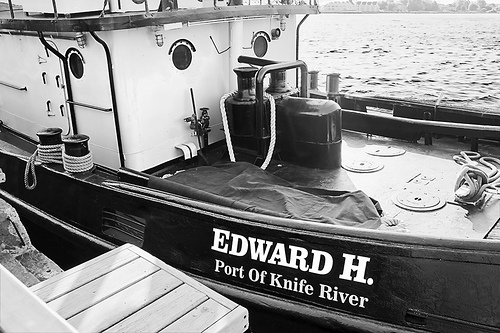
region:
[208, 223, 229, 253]
a letter is written in white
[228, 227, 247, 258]
a letter is written in white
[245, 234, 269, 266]
a letter is written in white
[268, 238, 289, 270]
a letter is written in white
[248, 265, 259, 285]
a letter is written in white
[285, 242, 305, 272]
a letter is written in white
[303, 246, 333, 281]
a letter is written in white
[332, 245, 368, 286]
a letter is written in white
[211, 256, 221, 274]
a letter is written in white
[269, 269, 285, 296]
a letter is written in white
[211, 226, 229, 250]
a letter is written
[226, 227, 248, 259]
a letter is written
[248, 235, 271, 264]
a letter is written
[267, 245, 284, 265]
a letter is written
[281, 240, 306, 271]
a letter is written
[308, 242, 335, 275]
a letter is written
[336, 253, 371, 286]
a letter is written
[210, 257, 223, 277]
a letter is written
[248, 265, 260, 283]
a letter is written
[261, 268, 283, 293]
a letter is written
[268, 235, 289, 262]
a letter is written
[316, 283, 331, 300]
a letter is written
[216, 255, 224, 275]
a letter is written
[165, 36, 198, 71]
A portal in a boat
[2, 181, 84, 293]
A stone stepping going down to the river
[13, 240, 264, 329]
A wooden dock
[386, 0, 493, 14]
Trees on the other side of a river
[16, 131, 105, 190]
Rope wrapped round and round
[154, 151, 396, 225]
A trap laid out on the deck of a boat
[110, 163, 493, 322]
The name of a boat painted on its side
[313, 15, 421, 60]
Sunlight shining on water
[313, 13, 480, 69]
A flowing river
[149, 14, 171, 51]
A light with a protective cage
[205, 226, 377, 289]
EDWARD H.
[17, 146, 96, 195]
two windy ship ropes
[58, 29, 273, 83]
three dark portholes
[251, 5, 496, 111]
one ocean with small wavelets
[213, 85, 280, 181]
big thick white rope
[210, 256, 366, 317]
Port of Knife River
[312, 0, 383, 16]
boat in the distance, against shoreline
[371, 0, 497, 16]
buildings+trees+things @ distant shoreline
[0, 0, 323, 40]
roof atop ship's cabin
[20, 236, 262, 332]
five white wooden slats